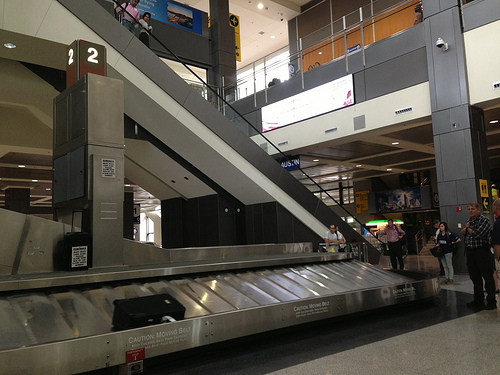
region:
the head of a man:
[456, 193, 490, 217]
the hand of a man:
[454, 216, 481, 233]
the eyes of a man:
[456, 193, 490, 215]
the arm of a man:
[446, 210, 496, 253]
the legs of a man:
[454, 257, 495, 325]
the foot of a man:
[451, 291, 493, 323]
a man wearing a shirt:
[444, 189, 496, 254]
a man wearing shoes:
[444, 292, 496, 334]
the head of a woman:
[427, 208, 467, 243]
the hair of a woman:
[431, 212, 456, 247]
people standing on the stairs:
[121, 3, 180, 48]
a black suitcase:
[111, 293, 188, 333]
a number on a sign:
[66, 40, 104, 75]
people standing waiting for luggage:
[345, 205, 496, 254]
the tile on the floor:
[283, 329, 485, 368]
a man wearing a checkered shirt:
[463, 200, 498, 287]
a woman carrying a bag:
[430, 220, 455, 275]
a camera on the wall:
[435, 37, 446, 48]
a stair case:
[133, 23, 390, 270]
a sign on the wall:
[259, 74, 370, 129]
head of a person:
[460, 196, 481, 214]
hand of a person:
[455, 222, 485, 244]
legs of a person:
[463, 253, 498, 321]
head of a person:
[433, 219, 448, 231]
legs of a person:
[439, 255, 463, 286]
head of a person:
[382, 215, 399, 225]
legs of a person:
[386, 246, 413, 284]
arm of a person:
[395, 226, 407, 237]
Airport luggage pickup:
[0, 0, 499, 374]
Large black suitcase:
[107, 290, 185, 333]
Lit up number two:
[65, 38, 106, 70]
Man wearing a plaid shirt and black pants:
[460, 200, 497, 312]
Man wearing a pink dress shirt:
[377, 218, 409, 272]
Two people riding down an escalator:
[114, 0, 154, 52]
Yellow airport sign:
[206, 9, 241, 61]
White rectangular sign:
[259, 73, 354, 134]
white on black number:
[66, 39, 107, 73]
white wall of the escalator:
[0, 0, 326, 242]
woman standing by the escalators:
[432, 221, 455, 281]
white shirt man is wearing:
[322, 227, 343, 239]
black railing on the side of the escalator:
[115, 3, 397, 258]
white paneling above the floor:
[246, 80, 429, 155]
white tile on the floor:
[272, 312, 497, 372]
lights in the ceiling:
[12, 163, 52, 192]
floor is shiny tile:
[324, 315, 495, 372]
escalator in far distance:
[51, 10, 353, 256]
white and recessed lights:
[308, 113, 425, 193]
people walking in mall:
[357, 202, 497, 322]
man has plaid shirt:
[449, 204, 495, 266]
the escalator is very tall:
[1, 0, 385, 262]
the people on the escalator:
[1, 0, 386, 260]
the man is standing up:
[378, 218, 407, 271]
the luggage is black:
[113, 293, 185, 331]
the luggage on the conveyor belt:
[1, 256, 439, 373]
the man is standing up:
[461, 202, 497, 309]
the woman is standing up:
[433, 222, 460, 284]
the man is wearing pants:
[460, 202, 498, 308]